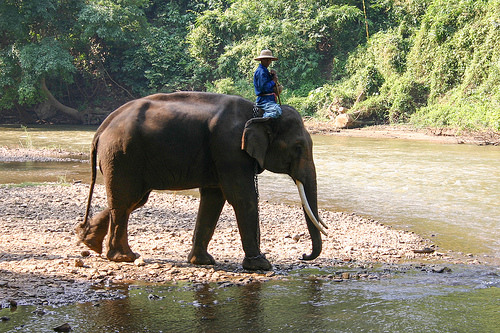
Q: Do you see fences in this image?
A: No, there are no fences.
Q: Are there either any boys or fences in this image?
A: No, there are no fences or boys.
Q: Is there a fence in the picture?
A: No, there are no fences.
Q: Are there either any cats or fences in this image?
A: No, there are no fences or cats.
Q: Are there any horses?
A: No, there are no horses.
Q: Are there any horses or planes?
A: No, there are no horses or planes.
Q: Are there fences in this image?
A: No, there are no fences.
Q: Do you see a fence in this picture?
A: No, there are no fences.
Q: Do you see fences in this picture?
A: No, there are no fences.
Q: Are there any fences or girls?
A: No, there are no fences or girls.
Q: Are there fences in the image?
A: No, there are no fences.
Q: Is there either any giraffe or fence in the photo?
A: No, there are no fences or giraffes.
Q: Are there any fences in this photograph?
A: No, there are no fences.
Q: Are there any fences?
A: No, there are no fences.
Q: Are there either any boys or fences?
A: No, there are no fences or boys.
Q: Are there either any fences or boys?
A: No, there are no fences or boys.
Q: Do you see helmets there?
A: No, there are no helmets.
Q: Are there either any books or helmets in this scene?
A: No, there are no helmets or books.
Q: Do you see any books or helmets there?
A: No, there are no helmets or books.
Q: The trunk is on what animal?
A: The trunk is on the elephant.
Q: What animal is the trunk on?
A: The trunk is on the elephant.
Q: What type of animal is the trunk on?
A: The trunk is on the elephant.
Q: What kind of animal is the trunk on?
A: The trunk is on the elephant.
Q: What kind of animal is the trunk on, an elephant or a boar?
A: The trunk is on an elephant.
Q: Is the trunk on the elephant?
A: Yes, the trunk is on the elephant.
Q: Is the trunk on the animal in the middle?
A: Yes, the trunk is on the elephant.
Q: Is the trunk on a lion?
A: No, the trunk is on the elephant.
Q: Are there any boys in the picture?
A: No, there are no boys.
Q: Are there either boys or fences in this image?
A: No, there are no boys or fences.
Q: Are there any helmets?
A: No, there are no helmets.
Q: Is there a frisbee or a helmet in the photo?
A: No, there are no helmets or frisbees.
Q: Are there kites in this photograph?
A: No, there are no kites.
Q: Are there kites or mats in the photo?
A: No, there are no kites or mats.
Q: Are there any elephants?
A: Yes, there is an elephant.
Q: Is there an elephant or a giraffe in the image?
A: Yes, there is an elephant.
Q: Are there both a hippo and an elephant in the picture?
A: No, there is an elephant but no hippos.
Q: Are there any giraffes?
A: No, there are no giraffes.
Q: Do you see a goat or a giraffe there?
A: No, there are no giraffes or goats.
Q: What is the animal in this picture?
A: The animal is an elephant.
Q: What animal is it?
A: The animal is an elephant.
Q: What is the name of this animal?
A: That is an elephant.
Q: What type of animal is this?
A: That is an elephant.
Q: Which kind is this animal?
A: That is an elephant.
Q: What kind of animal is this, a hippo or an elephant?
A: That is an elephant.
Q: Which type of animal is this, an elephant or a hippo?
A: That is an elephant.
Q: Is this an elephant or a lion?
A: This is an elephant.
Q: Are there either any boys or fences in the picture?
A: No, there are no fences or boys.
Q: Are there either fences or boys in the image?
A: No, there are no fences or boys.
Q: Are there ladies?
A: No, there are no ladies.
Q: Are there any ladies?
A: No, there are no ladies.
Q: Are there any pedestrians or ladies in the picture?
A: No, there are no ladies or pedestrians.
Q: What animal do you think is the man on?
A: The man is on the elephant.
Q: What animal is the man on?
A: The man is on the elephant.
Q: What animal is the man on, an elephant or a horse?
A: The man is on an elephant.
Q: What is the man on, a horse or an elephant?
A: The man is on an elephant.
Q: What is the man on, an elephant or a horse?
A: The man is on an elephant.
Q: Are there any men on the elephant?
A: Yes, there is a man on the elephant.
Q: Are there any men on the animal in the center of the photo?
A: Yes, there is a man on the elephant.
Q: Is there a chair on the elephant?
A: No, there is a man on the elephant.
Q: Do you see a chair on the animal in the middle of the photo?
A: No, there is a man on the elephant.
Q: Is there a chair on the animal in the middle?
A: No, there is a man on the elephant.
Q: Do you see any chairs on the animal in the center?
A: No, there is a man on the elephant.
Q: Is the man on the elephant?
A: Yes, the man is on the elephant.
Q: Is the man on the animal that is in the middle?
A: Yes, the man is on the elephant.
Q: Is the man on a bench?
A: No, the man is on the elephant.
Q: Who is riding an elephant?
A: The man is riding an elephant.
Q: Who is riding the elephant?
A: The man is riding an elephant.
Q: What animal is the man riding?
A: The man is riding an elephant.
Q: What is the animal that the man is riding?
A: The animal is an elephant.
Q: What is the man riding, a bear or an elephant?
A: The man is riding an elephant.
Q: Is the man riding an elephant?
A: Yes, the man is riding an elephant.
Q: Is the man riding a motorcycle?
A: No, the man is riding an elephant.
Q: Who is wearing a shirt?
A: The man is wearing a shirt.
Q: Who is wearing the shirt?
A: The man is wearing a shirt.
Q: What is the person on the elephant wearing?
A: The man is wearing a shirt.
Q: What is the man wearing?
A: The man is wearing a shirt.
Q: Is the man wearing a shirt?
A: Yes, the man is wearing a shirt.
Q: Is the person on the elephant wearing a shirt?
A: Yes, the man is wearing a shirt.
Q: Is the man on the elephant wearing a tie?
A: No, the man is wearing a shirt.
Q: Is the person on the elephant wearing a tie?
A: No, the man is wearing a shirt.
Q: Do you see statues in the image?
A: No, there are no statues.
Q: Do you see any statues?
A: No, there are no statues.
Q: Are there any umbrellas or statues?
A: No, there are no statues or umbrellas.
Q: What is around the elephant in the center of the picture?
A: The water is around the elephant.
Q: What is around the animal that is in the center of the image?
A: The water is around the elephant.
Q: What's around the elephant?
A: The water is around the elephant.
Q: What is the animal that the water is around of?
A: The animal is an elephant.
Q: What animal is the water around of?
A: The water is around the elephant.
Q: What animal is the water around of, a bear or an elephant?
A: The water is around an elephant.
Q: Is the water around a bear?
A: No, the water is around the elephant.